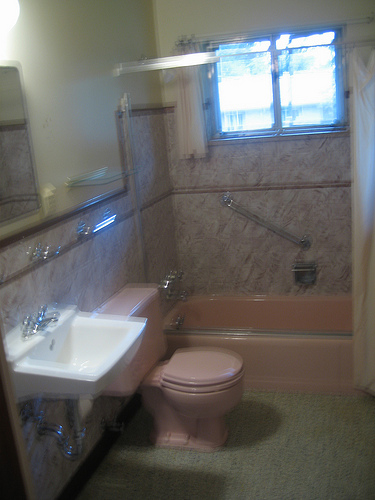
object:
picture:
[2, 1, 374, 499]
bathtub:
[165, 293, 351, 342]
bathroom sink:
[5, 305, 147, 395]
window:
[207, 30, 339, 135]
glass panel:
[213, 39, 273, 134]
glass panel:
[279, 32, 335, 125]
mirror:
[1, 66, 44, 212]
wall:
[31, 8, 109, 143]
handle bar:
[218, 193, 309, 248]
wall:
[180, 195, 227, 292]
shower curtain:
[348, 50, 373, 392]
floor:
[75, 391, 374, 499]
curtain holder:
[113, 44, 244, 78]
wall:
[2, 263, 101, 302]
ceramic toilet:
[161, 346, 245, 453]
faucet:
[159, 269, 173, 291]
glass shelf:
[68, 164, 120, 191]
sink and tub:
[2, 294, 355, 406]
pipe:
[35, 418, 84, 462]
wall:
[16, 444, 57, 497]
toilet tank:
[93, 279, 165, 396]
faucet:
[20, 303, 57, 335]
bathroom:
[0, 1, 374, 500]